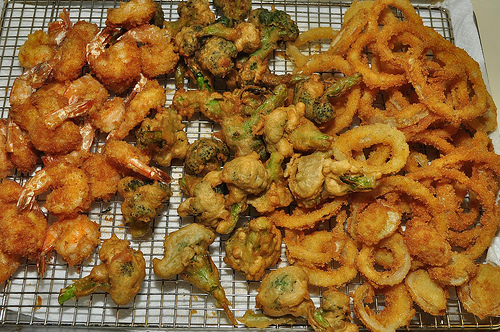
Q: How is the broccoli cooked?
A: Fried.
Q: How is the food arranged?
A: Clustered.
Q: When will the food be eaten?
A: For a snack.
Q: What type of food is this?
A: Tasty snacks.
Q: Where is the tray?
A: On the paper.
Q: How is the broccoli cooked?
A: With tempura.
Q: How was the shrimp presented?
A: With the tail.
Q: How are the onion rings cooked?
A: Fried in tempura.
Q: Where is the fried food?
A: On the rack.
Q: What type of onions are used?
A: White.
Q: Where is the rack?
A: Under the onion rings.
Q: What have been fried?
A: Vegetables.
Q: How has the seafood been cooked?
A: Fried in oil.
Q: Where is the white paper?
A: Under the drying rack.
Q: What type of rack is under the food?
A: Wire.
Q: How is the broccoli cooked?
A: Fried.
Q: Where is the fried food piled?
A: On the rack.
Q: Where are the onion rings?
A: On the rack.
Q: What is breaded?
A: Shrimp, broccoli, and onion rings.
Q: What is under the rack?
A: Paper towels.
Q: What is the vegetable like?
A: Fried and breaded.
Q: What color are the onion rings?
A: Golden.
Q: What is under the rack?
A: White paper.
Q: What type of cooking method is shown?
A: Frying.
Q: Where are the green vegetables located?
A: In the middle.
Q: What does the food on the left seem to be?
A: Shrimp.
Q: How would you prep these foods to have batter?
A: Add flour and fry.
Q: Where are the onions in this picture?
A: On the right side.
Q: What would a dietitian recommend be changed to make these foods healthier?
A: Cook them in a different way.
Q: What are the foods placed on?
A: A grid iron cooking sheet.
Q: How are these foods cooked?
A: Fried.